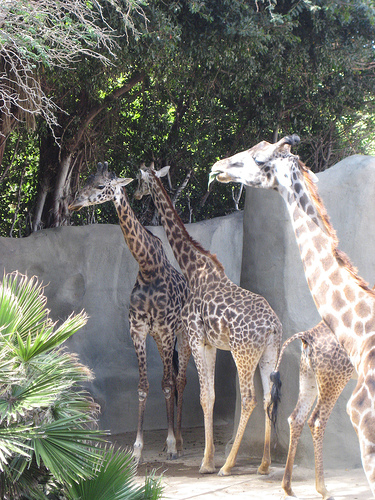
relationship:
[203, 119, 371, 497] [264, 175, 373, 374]
giraffe has neck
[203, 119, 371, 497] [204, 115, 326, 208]
giraffe has head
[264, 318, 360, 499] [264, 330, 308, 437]
giraffe has tail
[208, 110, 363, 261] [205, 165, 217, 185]
giraffe eating leaf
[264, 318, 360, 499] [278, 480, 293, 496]
giraffe has hoof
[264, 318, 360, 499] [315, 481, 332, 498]
giraffe has hoof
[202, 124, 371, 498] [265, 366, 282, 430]
giraffe has tail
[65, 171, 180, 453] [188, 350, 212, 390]
giraffe has giraffe leg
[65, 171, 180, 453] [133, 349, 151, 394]
giraffe has giraffe leg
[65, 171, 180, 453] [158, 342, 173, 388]
giraffe has giraffe leg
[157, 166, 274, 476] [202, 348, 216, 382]
giraffe has giraffe leg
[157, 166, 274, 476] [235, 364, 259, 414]
giraffe has giraffe leg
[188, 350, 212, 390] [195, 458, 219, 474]
giraffe leg has hoof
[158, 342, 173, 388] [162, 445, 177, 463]
giraffe leg has hoof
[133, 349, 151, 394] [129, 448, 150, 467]
giraffe leg has hoof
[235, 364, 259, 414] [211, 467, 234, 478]
giraffe leg has hoof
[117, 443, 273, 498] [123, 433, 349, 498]
shadow on ground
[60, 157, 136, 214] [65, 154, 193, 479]
giraffe face on giraffe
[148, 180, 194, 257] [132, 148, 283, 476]
long neck on giraffe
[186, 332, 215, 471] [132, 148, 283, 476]
leg on giraffe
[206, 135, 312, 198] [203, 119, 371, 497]
head on giraffe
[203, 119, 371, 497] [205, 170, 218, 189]
giraffe chewing food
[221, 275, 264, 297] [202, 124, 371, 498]
back on giraffe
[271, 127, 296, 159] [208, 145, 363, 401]
horns of giraffe